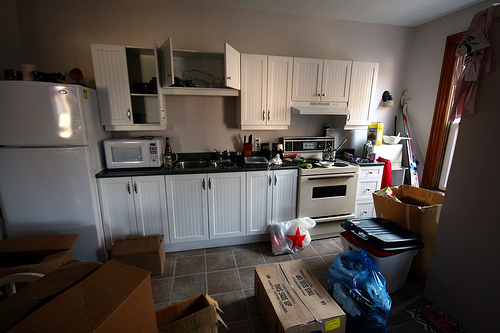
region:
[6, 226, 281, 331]
The cardboard boxes on the floor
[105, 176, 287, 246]
The cabinets are the color white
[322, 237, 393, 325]
The trash bag is the color blue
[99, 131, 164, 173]
The microwave on the counter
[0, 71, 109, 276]
The refrigerator is the color white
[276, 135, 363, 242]
The stove against the wall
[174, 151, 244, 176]
The sink is the color silver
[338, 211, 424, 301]
The buckets on the floor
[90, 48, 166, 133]
cabinet in a kitchen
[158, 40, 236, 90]
cabinet in a kitchen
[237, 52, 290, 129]
cabinet in a kitchen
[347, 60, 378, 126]
cabinet in a kitchen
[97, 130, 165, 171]
microwave on a counter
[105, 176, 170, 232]
cabinet in a kitchen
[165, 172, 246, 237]
cabinet in a kitchen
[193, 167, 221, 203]
handles on a cabinet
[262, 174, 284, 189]
handles on a cabinnet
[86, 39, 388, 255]
cabinets in the kitchen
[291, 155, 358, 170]
stove on top of the oven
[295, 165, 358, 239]
white oven in the kitchen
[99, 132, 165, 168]
white microwave on the counter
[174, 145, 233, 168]
sink in the counter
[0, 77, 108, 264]
white fridge next to the cabinets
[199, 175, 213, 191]
handles on the cabinets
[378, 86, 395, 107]
black and white light on the wall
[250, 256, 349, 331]
cardboard box next to the trash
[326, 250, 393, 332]
blue bag of trash on the floor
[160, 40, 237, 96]
the open cabinet doors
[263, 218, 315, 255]
the bag on the ground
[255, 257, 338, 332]
the cardboard box on the tile floor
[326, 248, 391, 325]
the blue bag on the ground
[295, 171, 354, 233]
the white oven door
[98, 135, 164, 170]
the microwave on the counter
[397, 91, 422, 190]
the skiis leaning on the wall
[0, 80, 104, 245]
the white fridge in the corner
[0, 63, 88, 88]
the stuff on top of the fridge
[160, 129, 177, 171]
the bottle on the counter top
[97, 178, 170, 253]
White cupboard doors in a kitchen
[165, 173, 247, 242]
White cupboard doors in a kitchen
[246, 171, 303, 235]
White cupboard doors in a kitchen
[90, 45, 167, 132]
White cupboard doors in a kitchen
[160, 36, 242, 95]
Open white cupboard doors in a kitchen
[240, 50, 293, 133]
White cupboard doors in a kitchen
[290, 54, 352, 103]
White cupboard doors in a kitchen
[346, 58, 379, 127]
White cupboard door in a kitchen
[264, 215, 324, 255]
White plastic bag on the ground with red star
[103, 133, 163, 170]
White microwave on the counter in a kitchen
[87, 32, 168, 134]
open white cupboard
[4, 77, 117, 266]
white refrigerator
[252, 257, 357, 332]
tan cardboard box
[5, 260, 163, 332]
tan cardboard box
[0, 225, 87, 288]
open tan cardboard box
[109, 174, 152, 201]
handles on a cabinet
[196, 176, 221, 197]
handles on a cabinet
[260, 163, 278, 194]
handles on a cabinet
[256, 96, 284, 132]
handles on a cabinet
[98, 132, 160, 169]
microwave on a counter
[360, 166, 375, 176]
knob on a drawer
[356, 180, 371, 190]
knob on a drawer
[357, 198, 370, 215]
knob on a drawer